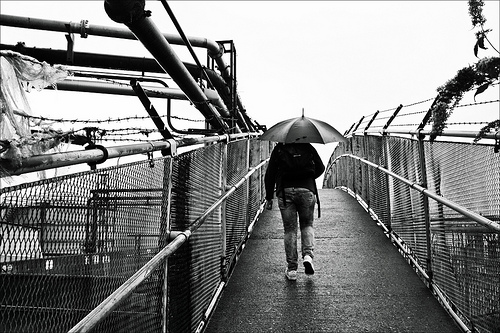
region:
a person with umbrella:
[255, 105, 342, 285]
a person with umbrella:
[248, 97, 342, 271]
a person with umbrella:
[249, 88, 349, 285]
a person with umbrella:
[251, 95, 346, 282]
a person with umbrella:
[247, 91, 352, 296]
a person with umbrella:
[235, 85, 354, 330]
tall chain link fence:
[390, 155, 477, 250]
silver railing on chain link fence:
[123, 213, 218, 274]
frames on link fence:
[79, 130, 113, 172]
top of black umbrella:
[295, 103, 311, 124]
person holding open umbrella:
[251, 102, 351, 164]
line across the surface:
[315, 226, 360, 246]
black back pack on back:
[265, 140, 329, 188]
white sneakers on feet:
[282, 246, 342, 284]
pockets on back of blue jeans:
[267, 184, 317, 207]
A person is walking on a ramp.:
[258, 110, 353, 291]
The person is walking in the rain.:
[255, 100, 350, 292]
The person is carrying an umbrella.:
[258, 102, 348, 287]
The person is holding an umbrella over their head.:
[242, 93, 354, 289]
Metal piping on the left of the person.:
[11, 6, 266, 168]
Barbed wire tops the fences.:
[3, 66, 497, 141]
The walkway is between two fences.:
[213, 111, 498, 328]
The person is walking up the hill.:
[245, 112, 352, 287]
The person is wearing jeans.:
[253, 109, 351, 284]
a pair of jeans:
[276, 180, 328, 255]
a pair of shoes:
[286, 250, 316, 290]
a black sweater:
[263, 140, 322, 189]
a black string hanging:
[306, 190, 324, 223]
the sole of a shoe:
[301, 259, 313, 274]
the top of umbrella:
[256, 104, 346, 143]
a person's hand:
[256, 196, 279, 215]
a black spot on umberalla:
[291, 133, 308, 145]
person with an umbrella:
[216, 85, 417, 285]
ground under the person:
[321, 223, 375, 294]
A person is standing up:
[249, 96, 339, 308]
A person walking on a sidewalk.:
[253, 95, 323, 262]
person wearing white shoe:
[284, 265, 299, 282]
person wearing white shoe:
[302, 254, 313, 276]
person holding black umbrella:
[256, 107, 346, 145]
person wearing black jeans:
[276, 185, 315, 269]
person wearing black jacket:
[264, 144, 326, 195]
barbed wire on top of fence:
[354, 81, 498, 124]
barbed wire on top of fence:
[354, 121, 497, 129]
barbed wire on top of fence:
[1, 105, 203, 122]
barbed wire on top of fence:
[57, 66, 167, 97]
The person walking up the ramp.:
[262, 139, 332, 282]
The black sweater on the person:
[263, 141, 326, 199]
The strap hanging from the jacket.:
[316, 196, 323, 218]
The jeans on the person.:
[275, 186, 317, 272]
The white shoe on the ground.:
[283, 264, 299, 281]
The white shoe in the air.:
[301, 254, 317, 276]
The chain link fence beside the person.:
[3, 129, 271, 331]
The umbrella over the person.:
[249, 116, 349, 144]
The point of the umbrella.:
[301, 106, 306, 116]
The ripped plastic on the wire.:
[0, 47, 77, 164]